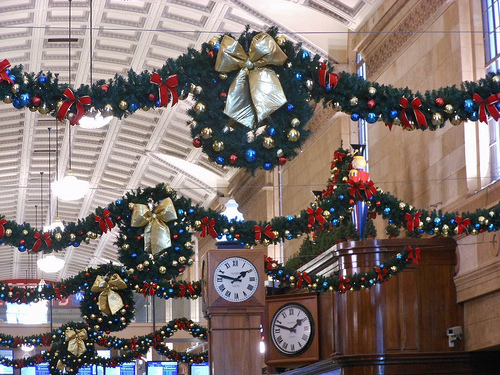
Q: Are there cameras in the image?
A: Yes, there is a camera.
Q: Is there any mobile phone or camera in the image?
A: Yes, there is a camera.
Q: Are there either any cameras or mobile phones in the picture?
A: Yes, there is a camera.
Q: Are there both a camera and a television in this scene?
A: No, there is a camera but no televisions.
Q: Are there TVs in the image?
A: No, there are no tvs.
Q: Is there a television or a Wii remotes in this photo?
A: No, there are no televisions or Wii controllers.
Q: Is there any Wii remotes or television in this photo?
A: No, there are no televisions or Wii controllers.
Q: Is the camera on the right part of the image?
A: Yes, the camera is on the right of the image.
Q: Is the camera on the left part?
A: No, the camera is on the right of the image.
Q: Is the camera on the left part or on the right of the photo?
A: The camera is on the right of the image.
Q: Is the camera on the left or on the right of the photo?
A: The camera is on the right of the image.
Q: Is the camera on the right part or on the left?
A: The camera is on the right of the image.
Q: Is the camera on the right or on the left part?
A: The camera is on the right of the image.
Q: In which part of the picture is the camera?
A: The camera is on the right of the image.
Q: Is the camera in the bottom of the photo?
A: Yes, the camera is in the bottom of the image.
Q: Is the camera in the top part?
A: No, the camera is in the bottom of the image.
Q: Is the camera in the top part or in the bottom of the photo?
A: The camera is in the bottom of the image.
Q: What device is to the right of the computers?
A: The device is a camera.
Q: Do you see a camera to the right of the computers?
A: Yes, there is a camera to the right of the computers.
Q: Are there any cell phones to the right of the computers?
A: No, there is a camera to the right of the computers.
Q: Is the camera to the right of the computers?
A: Yes, the camera is to the right of the computers.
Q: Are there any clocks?
A: Yes, there is a clock.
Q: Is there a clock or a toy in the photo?
A: Yes, there is a clock.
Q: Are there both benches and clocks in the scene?
A: No, there is a clock but no benches.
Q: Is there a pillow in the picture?
A: No, there are no pillows.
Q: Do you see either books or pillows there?
A: No, there are no pillows or books.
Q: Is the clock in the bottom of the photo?
A: Yes, the clock is in the bottom of the image.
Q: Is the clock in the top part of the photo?
A: No, the clock is in the bottom of the image.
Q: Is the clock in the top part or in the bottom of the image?
A: The clock is in the bottom of the image.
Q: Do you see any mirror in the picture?
A: No, there are no mirrors.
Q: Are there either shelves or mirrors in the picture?
A: No, there are no mirrors or shelves.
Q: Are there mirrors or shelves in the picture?
A: No, there are no mirrors or shelves.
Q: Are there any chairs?
A: No, there are no chairs.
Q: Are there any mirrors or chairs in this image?
A: No, there are no chairs or mirrors.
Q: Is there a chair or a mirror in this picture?
A: No, there are no chairs or mirrors.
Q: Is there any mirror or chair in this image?
A: No, there are no chairs or mirrors.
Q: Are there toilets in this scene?
A: No, there are no toilets.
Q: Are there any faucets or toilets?
A: No, there are no toilets or faucets.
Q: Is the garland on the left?
A: Yes, the garland is on the left of the image.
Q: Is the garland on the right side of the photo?
A: No, the garland is on the left of the image.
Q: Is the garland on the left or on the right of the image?
A: The garland is on the left of the image.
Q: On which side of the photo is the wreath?
A: The wreath is on the left of the image.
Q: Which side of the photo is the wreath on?
A: The wreath is on the left of the image.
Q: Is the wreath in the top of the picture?
A: Yes, the wreath is in the top of the image.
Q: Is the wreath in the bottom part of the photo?
A: No, the wreath is in the top of the image.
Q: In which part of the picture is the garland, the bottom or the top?
A: The garland is in the top of the image.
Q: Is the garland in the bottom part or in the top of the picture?
A: The garland is in the top of the image.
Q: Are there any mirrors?
A: No, there are no mirrors.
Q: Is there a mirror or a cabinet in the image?
A: No, there are no mirrors or cabinets.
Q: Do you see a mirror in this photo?
A: No, there are no mirrors.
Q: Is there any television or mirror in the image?
A: No, there are no mirrors or televisions.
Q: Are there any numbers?
A: Yes, there are numbers.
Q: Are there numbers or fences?
A: Yes, there are numbers.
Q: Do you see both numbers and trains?
A: No, there are numbers but no trains.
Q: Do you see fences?
A: No, there are no fences.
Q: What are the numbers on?
A: The numbers are on the clock.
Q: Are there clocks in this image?
A: Yes, there is a clock.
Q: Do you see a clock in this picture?
A: Yes, there is a clock.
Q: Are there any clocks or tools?
A: Yes, there is a clock.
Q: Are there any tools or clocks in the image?
A: Yes, there is a clock.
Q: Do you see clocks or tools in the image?
A: Yes, there is a clock.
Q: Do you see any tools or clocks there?
A: Yes, there is a clock.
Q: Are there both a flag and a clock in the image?
A: No, there is a clock but no flags.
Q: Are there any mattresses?
A: No, there are no mattresses.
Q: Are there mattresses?
A: No, there are no mattresses.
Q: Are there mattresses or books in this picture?
A: No, there are no mattresses or books.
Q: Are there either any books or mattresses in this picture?
A: No, there are no mattresses or books.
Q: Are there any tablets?
A: No, there are no tablets.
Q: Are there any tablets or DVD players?
A: No, there are no tablets or DVD players.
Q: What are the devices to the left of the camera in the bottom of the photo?
A: The devices are computers.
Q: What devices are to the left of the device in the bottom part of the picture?
A: The devices are computers.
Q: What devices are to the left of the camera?
A: The devices are computers.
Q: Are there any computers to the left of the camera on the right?
A: Yes, there are computers to the left of the camera.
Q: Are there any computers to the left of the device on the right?
A: Yes, there are computers to the left of the camera.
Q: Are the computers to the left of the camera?
A: Yes, the computers are to the left of the camera.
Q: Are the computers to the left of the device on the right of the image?
A: Yes, the computers are to the left of the camera.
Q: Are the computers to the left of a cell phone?
A: No, the computers are to the left of the camera.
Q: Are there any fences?
A: No, there are no fences.